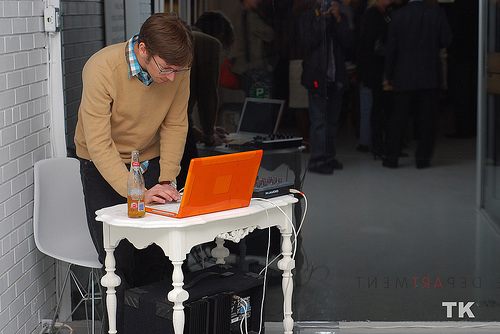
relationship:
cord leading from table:
[250, 197, 272, 331] [94, 185, 297, 332]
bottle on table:
[128, 147, 148, 217] [94, 185, 297, 332]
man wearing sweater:
[71, 12, 191, 333] [72, 34, 192, 198]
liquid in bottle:
[127, 194, 147, 219] [128, 147, 148, 217]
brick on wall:
[15, 54, 36, 70] [2, 2, 73, 318]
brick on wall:
[10, 84, 41, 108] [2, 2, 73, 318]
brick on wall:
[19, 266, 48, 283] [2, 2, 73, 318]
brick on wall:
[26, 272, 54, 309] [2, 2, 73, 318]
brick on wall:
[5, 4, 47, 29] [2, 2, 73, 318]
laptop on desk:
[141, 142, 264, 217] [88, 183, 308, 333]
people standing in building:
[300, 3, 453, 168] [3, 3, 489, 329]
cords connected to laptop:
[258, 185, 309, 309] [128, 140, 263, 222]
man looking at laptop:
[85, 26, 265, 274] [145, 149, 263, 220]